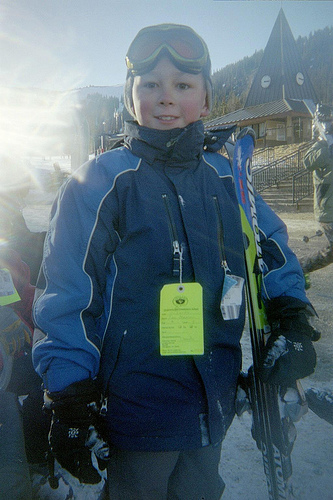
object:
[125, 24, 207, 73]
goggles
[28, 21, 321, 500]
boy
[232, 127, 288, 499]
skis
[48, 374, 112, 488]
gloves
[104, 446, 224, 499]
blue jeans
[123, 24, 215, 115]
hat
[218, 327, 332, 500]
snow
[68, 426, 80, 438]
logo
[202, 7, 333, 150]
ski lodge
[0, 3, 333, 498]
background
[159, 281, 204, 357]
tag